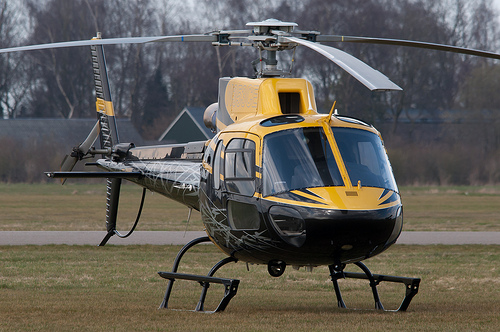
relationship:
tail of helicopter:
[84, 138, 199, 211] [2, 0, 499, 317]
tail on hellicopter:
[86, 32, 124, 248] [0, 16, 498, 309]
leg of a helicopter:
[326, 258, 418, 314] [185, 51, 470, 302]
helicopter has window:
[2, 0, 499, 317] [328, 119, 398, 191]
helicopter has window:
[2, 0, 499, 317] [258, 125, 349, 195]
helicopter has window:
[2, 0, 499, 317] [207, 132, 256, 196]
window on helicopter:
[258, 125, 349, 195] [2, 0, 499, 317]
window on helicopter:
[325, 115, 401, 202] [2, 0, 499, 317]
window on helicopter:
[224, 132, 261, 202] [2, 0, 499, 317]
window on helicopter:
[205, 134, 224, 196] [2, 0, 499, 317]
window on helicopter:
[220, 192, 266, 238] [2, 0, 499, 317]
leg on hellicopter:
[151, 230, 245, 320] [0, 16, 498, 309]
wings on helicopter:
[2, 17, 499, 88] [2, 0, 499, 317]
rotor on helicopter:
[277, 34, 402, 93] [0, 16, 499, 314]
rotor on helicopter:
[321, 27, 488, 57] [0, 16, 499, 314]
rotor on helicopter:
[6, 36, 233, 50] [0, 16, 499, 314]